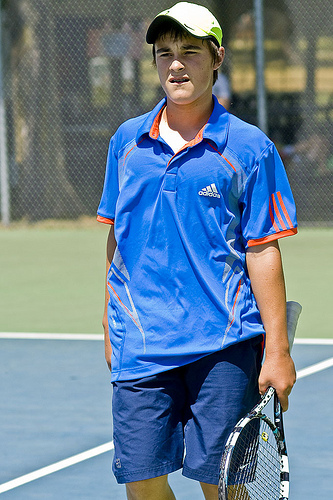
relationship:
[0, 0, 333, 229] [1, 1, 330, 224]
fence by fence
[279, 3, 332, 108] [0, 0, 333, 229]
trees behind fence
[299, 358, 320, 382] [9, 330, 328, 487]
line on pavement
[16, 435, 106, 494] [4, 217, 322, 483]
line on pavement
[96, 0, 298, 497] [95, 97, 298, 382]
boy wearing shirt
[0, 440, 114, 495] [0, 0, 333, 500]
line on court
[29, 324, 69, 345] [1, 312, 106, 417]
line on tennis court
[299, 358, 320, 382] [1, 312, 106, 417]
line on tennis court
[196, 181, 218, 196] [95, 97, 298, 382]
logo on shirt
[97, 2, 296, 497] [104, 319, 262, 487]
boy wearing shorts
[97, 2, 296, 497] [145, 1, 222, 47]
boy wearing hat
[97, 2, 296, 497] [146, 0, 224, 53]
boy wearing hat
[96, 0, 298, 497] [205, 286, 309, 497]
boy holding racket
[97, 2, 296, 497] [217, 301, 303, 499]
boy holding racket